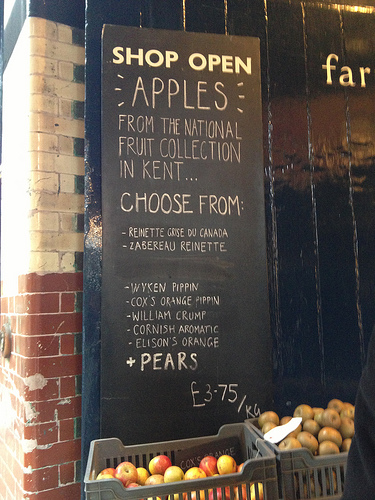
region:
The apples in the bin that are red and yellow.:
[92, 443, 262, 499]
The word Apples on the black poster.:
[127, 72, 229, 114]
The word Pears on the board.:
[137, 349, 202, 367]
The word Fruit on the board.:
[116, 133, 160, 162]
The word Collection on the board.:
[156, 136, 244, 165]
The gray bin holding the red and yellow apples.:
[66, 421, 274, 496]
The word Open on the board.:
[183, 45, 258, 81]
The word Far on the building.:
[320, 42, 372, 91]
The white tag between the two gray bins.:
[255, 420, 305, 445]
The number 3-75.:
[204, 376, 243, 404]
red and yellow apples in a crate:
[89, 422, 273, 498]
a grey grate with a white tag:
[84, 434, 277, 498]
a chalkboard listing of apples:
[101, 23, 247, 418]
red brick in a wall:
[16, 273, 76, 485]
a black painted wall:
[265, 2, 364, 369]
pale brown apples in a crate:
[255, 392, 353, 457]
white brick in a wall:
[21, 30, 77, 273]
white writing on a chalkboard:
[121, 48, 259, 416]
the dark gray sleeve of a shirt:
[344, 328, 374, 498]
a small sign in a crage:
[174, 435, 253, 484]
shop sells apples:
[95, 18, 271, 115]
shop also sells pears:
[113, 340, 214, 379]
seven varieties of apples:
[118, 190, 232, 348]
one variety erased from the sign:
[112, 226, 231, 306]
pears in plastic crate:
[255, 391, 345, 491]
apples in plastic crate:
[83, 424, 288, 493]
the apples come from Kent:
[111, 108, 261, 193]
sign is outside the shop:
[7, 7, 130, 285]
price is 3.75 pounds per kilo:
[178, 373, 281, 434]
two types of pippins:
[109, 261, 245, 314]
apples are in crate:
[95, 454, 266, 498]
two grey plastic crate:
[80, 417, 371, 498]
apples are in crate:
[254, 398, 352, 456]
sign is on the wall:
[81, 21, 277, 495]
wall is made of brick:
[4, 46, 98, 498]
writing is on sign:
[108, 44, 257, 424]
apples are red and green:
[96, 448, 263, 498]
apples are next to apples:
[96, 457, 264, 497]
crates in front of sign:
[83, 417, 373, 497]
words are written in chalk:
[124, 277, 224, 369]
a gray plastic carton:
[79, 416, 278, 497]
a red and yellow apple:
[110, 455, 137, 485]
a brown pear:
[322, 407, 342, 425]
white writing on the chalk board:
[122, 346, 205, 376]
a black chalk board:
[98, 22, 280, 473]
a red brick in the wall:
[15, 309, 85, 336]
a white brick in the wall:
[24, 113, 86, 137]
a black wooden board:
[262, 0, 330, 408]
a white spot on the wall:
[21, 368, 52, 393]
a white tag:
[262, 413, 306, 446]